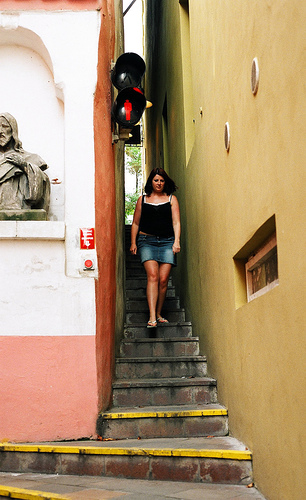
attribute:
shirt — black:
[134, 190, 181, 246]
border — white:
[140, 187, 173, 207]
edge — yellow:
[104, 411, 228, 417]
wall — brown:
[222, 302, 298, 462]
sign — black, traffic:
[107, 50, 148, 130]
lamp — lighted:
[104, 40, 163, 145]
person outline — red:
[122, 98, 132, 121]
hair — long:
[142, 168, 179, 194]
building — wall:
[1, 0, 300, 498]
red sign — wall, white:
[64, 225, 98, 279]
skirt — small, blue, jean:
[136, 224, 195, 279]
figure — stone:
[0, 108, 53, 222]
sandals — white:
[145, 316, 172, 329]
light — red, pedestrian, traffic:
[109, 50, 149, 134]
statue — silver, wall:
[2, 117, 48, 207]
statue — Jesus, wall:
[3, 111, 57, 220]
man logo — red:
[121, 97, 134, 125]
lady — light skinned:
[130, 167, 188, 297]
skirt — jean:
[139, 230, 177, 265]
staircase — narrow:
[99, 221, 254, 494]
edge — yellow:
[99, 408, 239, 423]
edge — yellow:
[98, 406, 258, 468]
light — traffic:
[112, 92, 150, 150]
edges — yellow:
[103, 410, 224, 420]